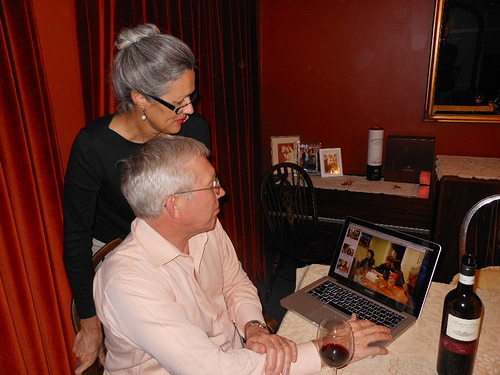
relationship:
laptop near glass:
[282, 219, 448, 348] [319, 314, 359, 373]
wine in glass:
[318, 340, 350, 365] [319, 314, 359, 373]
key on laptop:
[314, 290, 324, 298] [298, 233, 433, 318]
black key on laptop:
[337, 285, 344, 293] [273, 216, 446, 358]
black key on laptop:
[366, 303, 375, 318] [273, 216, 446, 358]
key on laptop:
[349, 289, 354, 297] [328, 283, 388, 312]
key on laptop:
[345, 292, 358, 306] [273, 216, 446, 358]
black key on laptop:
[313, 284, 328, 294] [307, 218, 424, 353]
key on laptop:
[319, 297, 404, 353] [271, 205, 436, 355]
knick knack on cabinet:
[320, 145, 345, 179] [267, 172, 434, 272]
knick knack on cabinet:
[320, 145, 345, 179] [262, 170, 434, 255]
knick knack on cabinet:
[365, 127, 385, 180] [262, 175, 450, 280]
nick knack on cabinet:
[381, 133, 441, 187] [271, 163, 468, 261]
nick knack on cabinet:
[416, 170, 433, 198] [266, 170, 436, 322]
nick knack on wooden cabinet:
[366, 120, 381, 177] [274, 169, 440, 246]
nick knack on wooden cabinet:
[381, 133, 441, 187] [274, 169, 440, 246]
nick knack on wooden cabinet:
[316, 147, 345, 177] [274, 169, 440, 246]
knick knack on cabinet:
[337, 175, 356, 187] [266, 170, 436, 322]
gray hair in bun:
[108, 19, 198, 113] [110, 19, 158, 51]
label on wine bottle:
[442, 316, 484, 343] [419, 252, 494, 358]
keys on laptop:
[333, 295, 355, 302] [273, 216, 446, 358]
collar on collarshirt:
[129, 214, 209, 271] [86, 212, 325, 372]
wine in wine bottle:
[437, 325, 477, 366] [419, 252, 493, 375]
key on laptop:
[349, 298, 354, 306] [273, 216, 446, 358]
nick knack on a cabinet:
[268, 132, 302, 172] [266, 170, 436, 322]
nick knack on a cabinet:
[302, 142, 317, 170] [266, 170, 436, 322]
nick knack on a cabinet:
[316, 147, 345, 177] [266, 170, 436, 322]